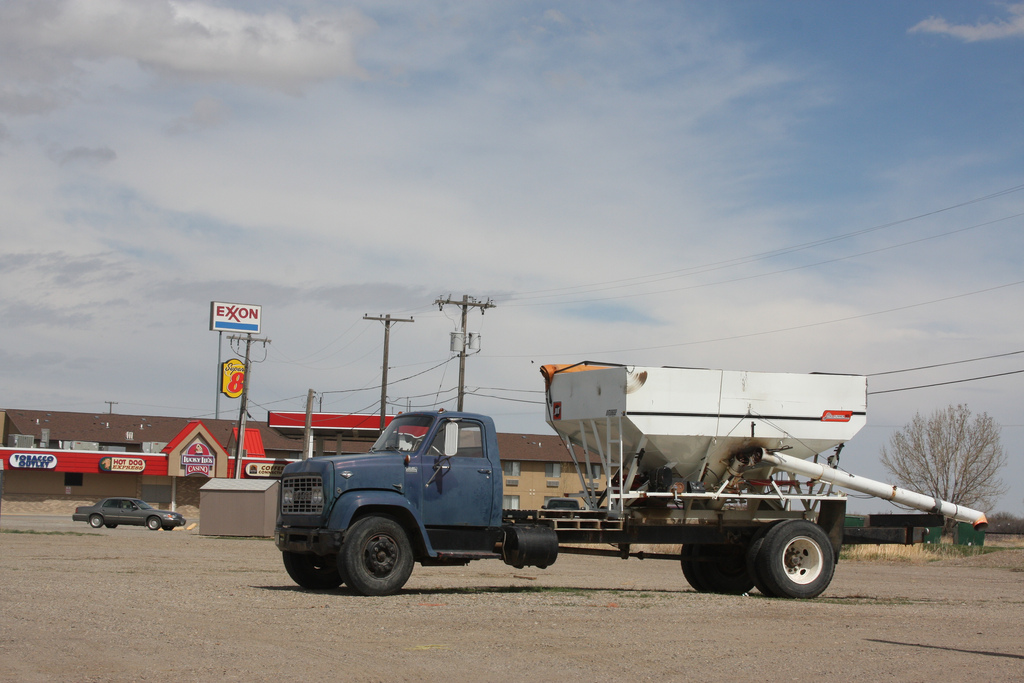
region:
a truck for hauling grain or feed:
[223, 328, 1023, 598]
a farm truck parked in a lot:
[265, 332, 1019, 633]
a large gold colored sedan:
[70, 490, 184, 545]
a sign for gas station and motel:
[177, 287, 276, 420]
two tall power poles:
[356, 282, 490, 382]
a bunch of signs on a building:
[0, 446, 299, 486]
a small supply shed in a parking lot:
[186, 462, 284, 549]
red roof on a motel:
[268, 398, 380, 437]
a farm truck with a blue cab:
[255, 367, 534, 621]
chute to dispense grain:
[751, 430, 989, 536]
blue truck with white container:
[276, 361, 991, 603]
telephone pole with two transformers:
[434, 291, 502, 416]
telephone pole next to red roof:
[362, 304, 414, 434]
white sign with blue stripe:
[205, 297, 266, 428]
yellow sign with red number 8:
[220, 355, 258, 403]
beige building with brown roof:
[0, 401, 620, 513]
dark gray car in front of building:
[72, 493, 189, 536]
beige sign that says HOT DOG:
[99, 453, 151, 474]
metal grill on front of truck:
[276, 469, 331, 523]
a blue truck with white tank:
[269, 344, 883, 614]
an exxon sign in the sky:
[204, 293, 269, 341]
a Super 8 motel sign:
[217, 351, 246, 405]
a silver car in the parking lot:
[69, 490, 191, 538]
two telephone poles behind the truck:
[335, 274, 504, 470]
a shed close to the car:
[182, 461, 293, 544]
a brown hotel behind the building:
[3, 389, 608, 539]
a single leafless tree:
[890, 395, 1018, 561]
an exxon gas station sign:
[209, 300, 264, 336]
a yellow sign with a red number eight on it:
[215, 354, 250, 400]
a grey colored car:
[68, 490, 192, 535]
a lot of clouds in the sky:
[9, 9, 997, 275]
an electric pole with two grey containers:
[430, 284, 501, 411]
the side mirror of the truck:
[422, 413, 464, 490]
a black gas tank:
[501, 512, 566, 570]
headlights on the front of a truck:
[274, 477, 332, 515]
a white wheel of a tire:
[777, 530, 826, 587]